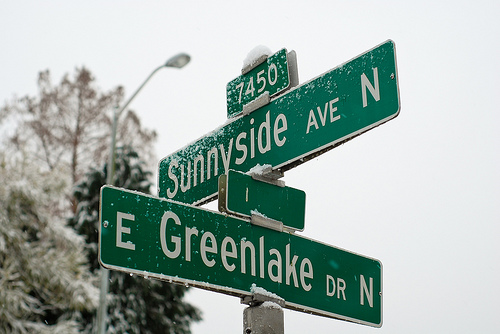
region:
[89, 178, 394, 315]
street sign on a post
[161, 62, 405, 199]
street sign on a post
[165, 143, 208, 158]
snow on the street sign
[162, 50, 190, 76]
light on a post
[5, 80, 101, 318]
a group of trees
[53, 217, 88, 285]
snow on the trees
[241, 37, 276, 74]
snow on the top of sign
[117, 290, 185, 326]
snow on the trees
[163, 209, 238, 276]
letters on street sign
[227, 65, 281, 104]
numbers on street sign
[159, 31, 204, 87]
silver metal street light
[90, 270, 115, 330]
silver metal street light pole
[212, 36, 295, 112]
street sign covered in snow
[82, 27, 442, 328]
cluster of green metal street signs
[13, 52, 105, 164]
tree covered in brown leaves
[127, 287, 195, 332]
green leaves on tree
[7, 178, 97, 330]
tree covered in snow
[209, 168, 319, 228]
faded green street sign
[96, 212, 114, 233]
silver bolt on green metal street sign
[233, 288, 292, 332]
silver metal street sign pole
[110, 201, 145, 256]
The letter is white.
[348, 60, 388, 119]
The letter is white.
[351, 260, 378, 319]
The letter is white.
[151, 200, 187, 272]
The letter is white.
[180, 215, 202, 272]
The letter is white.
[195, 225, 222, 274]
The letter is white.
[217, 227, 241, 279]
The letter is white.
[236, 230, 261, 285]
The letter is white.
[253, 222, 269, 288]
The letter is white.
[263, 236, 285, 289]
The letter is white.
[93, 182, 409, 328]
The street sign is on the bottom.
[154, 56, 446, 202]
The street sign is on the top.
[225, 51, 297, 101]
The small sign shows the block.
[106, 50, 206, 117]
The street light is almost as tall as the tree.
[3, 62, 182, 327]
The tree is tall.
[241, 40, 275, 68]
Snow is on top of the sign.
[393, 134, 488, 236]
The skies are gray.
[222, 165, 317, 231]
The small sign is empty.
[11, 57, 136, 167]
The tree is bare.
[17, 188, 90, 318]
The trees have snow on them.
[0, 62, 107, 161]
brown tree covered in dead leaves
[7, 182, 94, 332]
tree with green leaves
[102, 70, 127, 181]
silver metal street light pole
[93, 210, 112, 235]
silver metal bolt on street sign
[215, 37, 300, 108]
green metal street sign covered in snow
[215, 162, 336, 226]
faded blank street sign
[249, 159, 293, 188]
silver metal street sign brackets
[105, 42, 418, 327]
stacked metal street signs